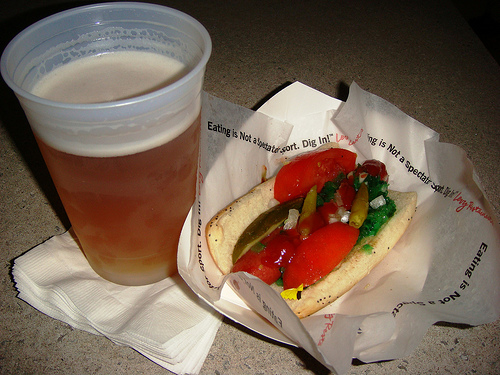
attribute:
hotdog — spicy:
[200, 137, 414, 307]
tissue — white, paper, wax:
[185, 71, 487, 369]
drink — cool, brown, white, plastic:
[0, 10, 216, 280]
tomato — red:
[269, 147, 358, 201]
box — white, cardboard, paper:
[165, 72, 444, 359]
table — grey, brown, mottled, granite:
[4, 4, 499, 371]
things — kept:
[6, 5, 448, 349]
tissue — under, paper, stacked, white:
[16, 186, 235, 374]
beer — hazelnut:
[22, 47, 201, 277]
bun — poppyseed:
[206, 158, 424, 321]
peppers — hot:
[297, 169, 374, 235]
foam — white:
[18, 43, 209, 141]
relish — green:
[310, 162, 393, 235]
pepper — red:
[270, 222, 374, 286]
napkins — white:
[29, 150, 226, 327]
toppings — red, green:
[235, 159, 396, 281]